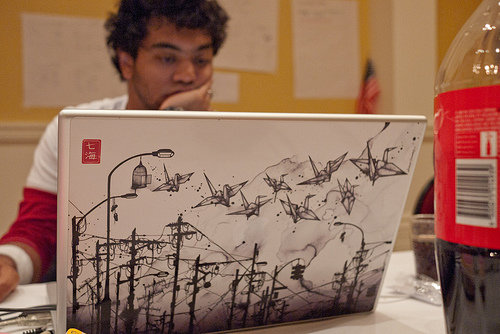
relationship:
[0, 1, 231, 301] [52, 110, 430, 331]
man on laptop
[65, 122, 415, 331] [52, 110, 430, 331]
design on laptop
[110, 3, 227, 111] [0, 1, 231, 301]
head on man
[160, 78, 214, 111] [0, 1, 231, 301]
hand on man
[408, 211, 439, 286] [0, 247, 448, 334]
glass on table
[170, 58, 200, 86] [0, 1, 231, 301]
nose on man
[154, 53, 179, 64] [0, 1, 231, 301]
eye on man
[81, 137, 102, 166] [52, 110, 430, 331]
symbol on laptop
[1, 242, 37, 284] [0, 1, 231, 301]
wristband on man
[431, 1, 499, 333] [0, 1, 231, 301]
bottle by man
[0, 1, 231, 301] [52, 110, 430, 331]
man by laptop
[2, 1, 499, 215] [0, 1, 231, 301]
wall behind man